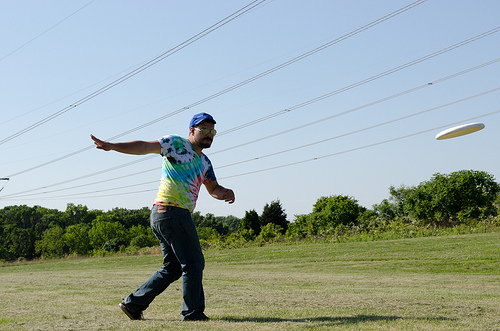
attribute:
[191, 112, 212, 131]
cap — blue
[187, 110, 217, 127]
cap — blue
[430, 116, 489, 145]
frisbee — white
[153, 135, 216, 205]
tee shirt — short sleeved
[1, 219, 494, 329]
grass — green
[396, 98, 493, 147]
frisbee — flying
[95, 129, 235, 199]
arms — stretched out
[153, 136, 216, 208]
shirt — colorful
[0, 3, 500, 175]
sky — blue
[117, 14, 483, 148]
wires — suspended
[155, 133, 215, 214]
shirt — tie dyed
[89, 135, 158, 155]
arm — extended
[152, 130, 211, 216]
shirt — colorful, tie dyed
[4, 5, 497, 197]
power lines — black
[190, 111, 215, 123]
hat — blue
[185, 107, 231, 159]
hat — blue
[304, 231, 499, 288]
grass — green